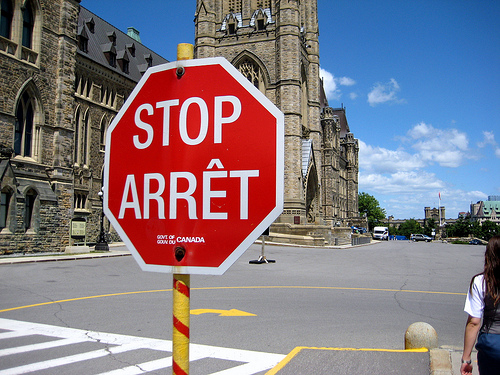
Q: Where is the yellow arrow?
A: Ground by crosswalk.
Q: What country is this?
A: Canada.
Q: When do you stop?
A: At sign.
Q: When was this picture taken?
A: Daytime.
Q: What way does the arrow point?
A: Right.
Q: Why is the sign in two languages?
A: Foreign country.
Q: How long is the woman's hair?
A: To butt.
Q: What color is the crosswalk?
A: White.